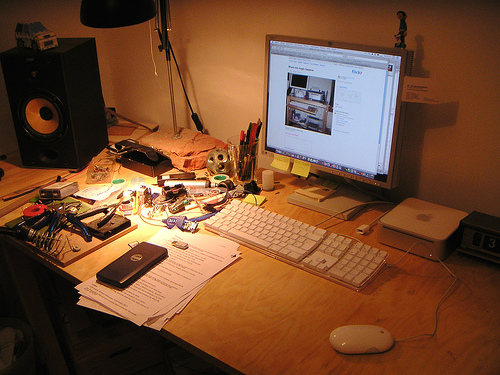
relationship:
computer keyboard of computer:
[204, 196, 388, 291] [377, 194, 466, 267]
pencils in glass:
[239, 118, 260, 147] [226, 139, 261, 186]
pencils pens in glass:
[238, 118, 261, 181] [226, 139, 261, 186]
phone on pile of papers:
[97, 241, 168, 288] [73, 227, 242, 332]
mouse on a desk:
[326, 316, 397, 356] [4, 115, 498, 370]